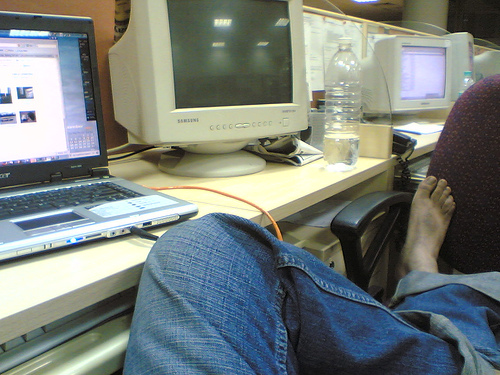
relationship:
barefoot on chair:
[396, 173, 456, 284] [327, 73, 498, 304]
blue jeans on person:
[123, 212, 499, 374] [118, 175, 498, 374]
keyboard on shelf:
[17, 283, 109, 370] [12, 292, 126, 372]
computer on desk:
[0, 9, 198, 265] [107, 3, 321, 187]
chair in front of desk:
[327, 73, 498, 304] [193, 175, 351, 248]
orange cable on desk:
[145, 182, 286, 247] [0, 98, 497, 372]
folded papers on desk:
[242, 134, 324, 166] [0, 119, 394, 373]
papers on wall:
[306, 21, 369, 89] [0, 0, 497, 156]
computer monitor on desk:
[106, 3, 311, 180] [243, 175, 305, 216]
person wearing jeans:
[118, 175, 498, 374] [82, 178, 499, 365]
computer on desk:
[0, 9, 198, 265] [0, 119, 394, 373]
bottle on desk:
[322, 37, 364, 173] [227, 168, 307, 217]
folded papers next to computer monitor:
[250, 138, 321, 168] [106, 3, 311, 180]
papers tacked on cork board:
[302, 14, 363, 92] [307, 86, 324, 107]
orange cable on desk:
[142, 185, 283, 242] [0, 119, 394, 373]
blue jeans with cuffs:
[123, 212, 499, 374] [390, 270, 499, 372]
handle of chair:
[329, 190, 414, 305] [327, 73, 498, 304]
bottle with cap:
[456, 69, 475, 98] [462, 70, 472, 75]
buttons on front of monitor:
[201, 124, 287, 137] [159, 6, 306, 118]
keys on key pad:
[0, 178, 142, 219] [6, 177, 203, 252]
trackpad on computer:
[13, 210, 83, 231] [0, 9, 198, 265]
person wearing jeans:
[118, 175, 498, 374] [237, 249, 345, 316]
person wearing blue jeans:
[118, 175, 498, 374] [121, 225, 499, 373]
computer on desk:
[0, 9, 198, 265] [0, 0, 393, 346]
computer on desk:
[0, 9, 198, 265] [0, 123, 392, 375]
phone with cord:
[378, 124, 426, 186] [394, 149, 417, 190]